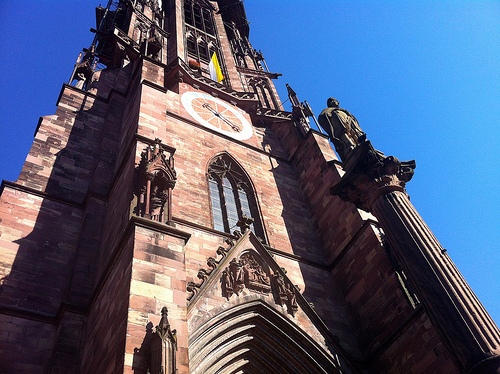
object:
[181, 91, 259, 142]
clock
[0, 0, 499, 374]
tower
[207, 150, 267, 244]
window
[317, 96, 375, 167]
statue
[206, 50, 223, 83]
flag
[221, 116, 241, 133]
hand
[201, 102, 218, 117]
hand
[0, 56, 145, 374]
shadow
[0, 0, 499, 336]
sky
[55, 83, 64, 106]
mark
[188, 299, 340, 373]
arch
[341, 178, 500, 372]
column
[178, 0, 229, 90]
window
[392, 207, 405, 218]
ridges